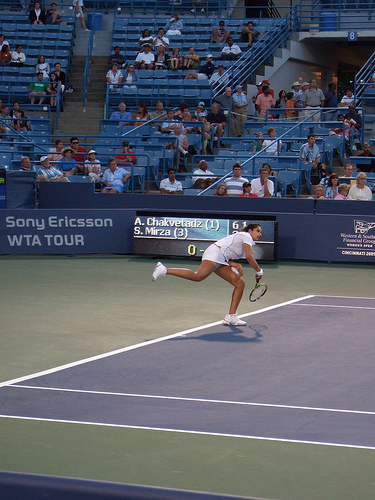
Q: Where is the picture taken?
A: Tennis court.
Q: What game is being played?
A: Tennis.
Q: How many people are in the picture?
A: One.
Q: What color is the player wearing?
A: White.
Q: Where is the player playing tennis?
A: Tennis court.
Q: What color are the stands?
A: Blue.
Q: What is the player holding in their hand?
A: Racket.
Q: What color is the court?
A: Green & blue.